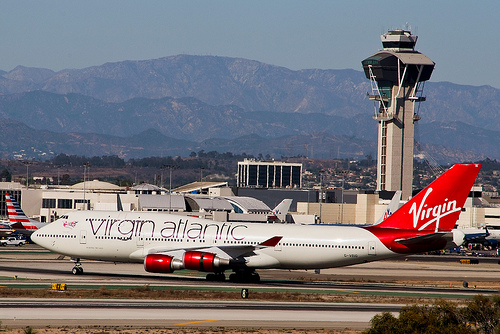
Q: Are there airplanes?
A: Yes, there are airplanes.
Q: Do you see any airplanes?
A: Yes, there are airplanes.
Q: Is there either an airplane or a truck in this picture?
A: Yes, there are airplanes.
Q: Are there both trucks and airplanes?
A: No, there are airplanes but no trucks.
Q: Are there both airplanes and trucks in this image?
A: No, there are airplanes but no trucks.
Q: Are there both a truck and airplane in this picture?
A: No, there are airplanes but no trucks.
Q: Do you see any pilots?
A: No, there are no pilots.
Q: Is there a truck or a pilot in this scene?
A: No, there are no pilots or trucks.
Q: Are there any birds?
A: No, there are no birds.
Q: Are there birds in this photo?
A: No, there are no birds.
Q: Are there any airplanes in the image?
A: Yes, there is an airplane.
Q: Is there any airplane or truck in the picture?
A: Yes, there is an airplane.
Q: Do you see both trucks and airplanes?
A: No, there is an airplane but no trucks.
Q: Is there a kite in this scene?
A: No, there are no kites.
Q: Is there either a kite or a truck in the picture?
A: No, there are no kites or trucks.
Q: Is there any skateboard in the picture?
A: No, there are no skateboards.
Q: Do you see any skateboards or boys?
A: No, there are no skateboards or boys.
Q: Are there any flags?
A: No, there are no flags.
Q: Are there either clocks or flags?
A: No, there are no flags or clocks.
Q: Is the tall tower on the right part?
A: Yes, the tower is on the right of the image.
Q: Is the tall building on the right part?
A: Yes, the tower is on the right of the image.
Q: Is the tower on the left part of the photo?
A: No, the tower is on the right of the image.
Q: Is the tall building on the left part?
A: No, the tower is on the right of the image.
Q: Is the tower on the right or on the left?
A: The tower is on the right of the image.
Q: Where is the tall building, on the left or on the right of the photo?
A: The tower is on the right of the image.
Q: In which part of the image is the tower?
A: The tower is on the right of the image.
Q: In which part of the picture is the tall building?
A: The tower is on the right of the image.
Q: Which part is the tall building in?
A: The tower is on the right of the image.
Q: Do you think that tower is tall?
A: Yes, the tower is tall.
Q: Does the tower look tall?
A: Yes, the tower is tall.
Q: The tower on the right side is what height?
A: The tower is tall.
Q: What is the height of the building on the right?
A: The tower is tall.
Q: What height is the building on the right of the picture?
A: The tower is tall.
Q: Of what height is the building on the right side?
A: The tower is tall.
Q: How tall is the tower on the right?
A: The tower is tall.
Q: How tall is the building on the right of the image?
A: The tower is tall.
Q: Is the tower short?
A: No, the tower is tall.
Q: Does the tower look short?
A: No, the tower is tall.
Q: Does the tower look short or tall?
A: The tower is tall.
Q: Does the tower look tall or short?
A: The tower is tall.